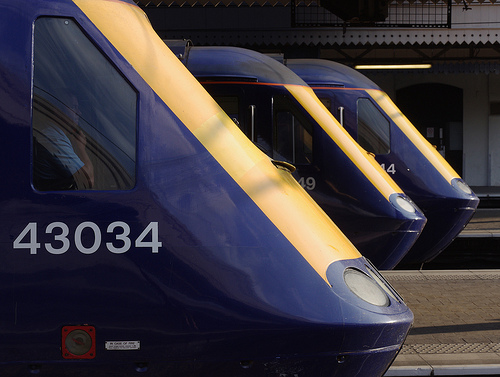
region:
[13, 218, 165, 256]
identification number on a train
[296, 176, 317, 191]
identification number on a train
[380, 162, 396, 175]
identification number on a train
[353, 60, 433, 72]
light at train station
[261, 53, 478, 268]
train parked at a train station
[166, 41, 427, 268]
train parked at train station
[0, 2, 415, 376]
train parked at train station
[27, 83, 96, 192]
person sitting in a train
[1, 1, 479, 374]
three trains at a station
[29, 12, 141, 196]
window on side of train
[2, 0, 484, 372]
three trains parked on tracks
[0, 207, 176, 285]
numbers 43034 on side of train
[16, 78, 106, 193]
man sitting inside train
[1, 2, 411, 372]
blue train with yellow stripe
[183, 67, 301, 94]
thin red line on top of train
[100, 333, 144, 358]
small sticker on side of train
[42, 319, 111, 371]
reflector on side of train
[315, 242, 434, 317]
headlights on front of train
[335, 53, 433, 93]
lights powered on in train depot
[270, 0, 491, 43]
metal grate above awning of building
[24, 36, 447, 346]
these are trains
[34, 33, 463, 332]
these are passenger trains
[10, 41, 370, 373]
the trains are blue and yellow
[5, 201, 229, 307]
these are numbers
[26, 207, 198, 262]
the train number is 43034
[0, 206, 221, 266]
the numbers are white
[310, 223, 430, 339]
these are head lights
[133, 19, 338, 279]
the front of the train is yellow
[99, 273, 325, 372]
the side of the train is blue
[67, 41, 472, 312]
these are three trains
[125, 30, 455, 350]
three trains in a row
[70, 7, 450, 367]
the trains are the same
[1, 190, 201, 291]
numbers are on the side of the train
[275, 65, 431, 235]
the front of the train is yellow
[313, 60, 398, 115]
a stripe on the top of the train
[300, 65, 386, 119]
the stripe is red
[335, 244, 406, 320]
the headlight is off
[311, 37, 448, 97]
the light is on